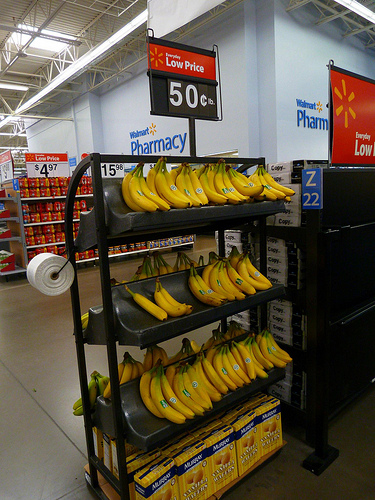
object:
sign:
[147, 36, 219, 121]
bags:
[25, 251, 75, 297]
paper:
[273, 212, 300, 227]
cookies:
[130, 458, 178, 498]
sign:
[301, 169, 323, 211]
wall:
[275, 0, 374, 163]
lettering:
[297, 109, 304, 128]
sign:
[326, 58, 374, 168]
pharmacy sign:
[128, 122, 188, 156]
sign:
[25, 151, 70, 178]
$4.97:
[34, 163, 58, 177]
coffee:
[27, 176, 40, 187]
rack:
[61, 146, 304, 500]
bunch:
[122, 162, 171, 214]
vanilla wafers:
[233, 411, 267, 476]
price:
[168, 82, 214, 109]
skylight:
[8, 23, 76, 56]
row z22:
[301, 165, 374, 435]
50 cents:
[169, 80, 207, 109]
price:
[34, 163, 57, 177]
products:
[251, 154, 296, 205]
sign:
[91, 152, 125, 179]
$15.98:
[102, 163, 124, 177]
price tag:
[165, 75, 219, 115]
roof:
[1, 0, 239, 126]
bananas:
[128, 165, 158, 213]